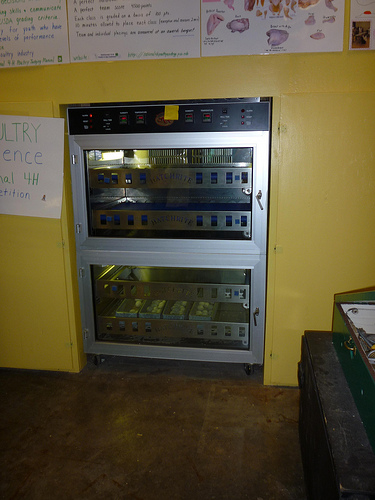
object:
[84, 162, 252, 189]
shelf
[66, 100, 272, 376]
oven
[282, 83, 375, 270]
wall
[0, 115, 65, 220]
sign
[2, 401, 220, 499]
floor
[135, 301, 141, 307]
bread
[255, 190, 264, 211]
handle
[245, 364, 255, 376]
wheel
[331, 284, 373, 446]
box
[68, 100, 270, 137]
controls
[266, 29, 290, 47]
picture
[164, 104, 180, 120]
sticky note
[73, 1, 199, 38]
writing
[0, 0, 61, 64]
writing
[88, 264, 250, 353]
racks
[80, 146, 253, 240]
window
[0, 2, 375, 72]
signs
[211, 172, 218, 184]
object